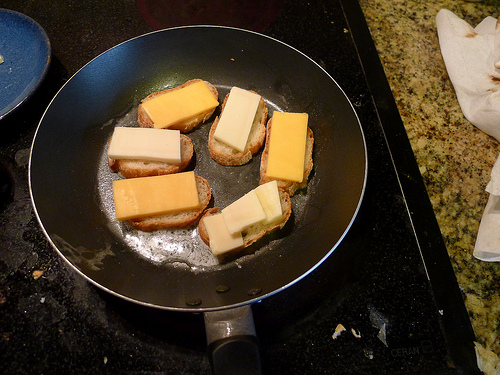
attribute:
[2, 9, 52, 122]
plate — blue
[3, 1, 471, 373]
stove — dirty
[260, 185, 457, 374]
stove — black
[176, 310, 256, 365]
handle — black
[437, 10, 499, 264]
towel — white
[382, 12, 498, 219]
counter top — granite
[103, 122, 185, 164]
cheese — white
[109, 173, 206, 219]
cheese — yellow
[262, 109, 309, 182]
cheese — yellow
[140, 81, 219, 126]
cheese — yellow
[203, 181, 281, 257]
cheese — white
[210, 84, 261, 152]
cheese — white